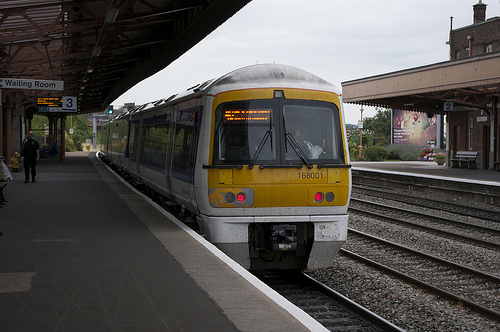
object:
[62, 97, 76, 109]
sign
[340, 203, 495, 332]
tracks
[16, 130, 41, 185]
person standing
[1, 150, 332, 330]
train platform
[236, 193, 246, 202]
headlight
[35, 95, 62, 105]
sign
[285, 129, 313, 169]
windshield wiper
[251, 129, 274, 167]
windshield wiper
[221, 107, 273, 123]
orange sign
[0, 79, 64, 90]
sign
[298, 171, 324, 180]
print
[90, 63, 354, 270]
train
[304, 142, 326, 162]
bag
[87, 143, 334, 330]
curb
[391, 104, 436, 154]
clock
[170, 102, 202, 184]
window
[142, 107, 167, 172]
window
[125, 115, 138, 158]
window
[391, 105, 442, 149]
poster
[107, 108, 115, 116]
signal light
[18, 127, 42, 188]
man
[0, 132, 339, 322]
platform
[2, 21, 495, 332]
station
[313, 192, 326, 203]
red light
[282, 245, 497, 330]
track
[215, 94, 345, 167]
train windshield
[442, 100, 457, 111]
sign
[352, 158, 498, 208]
platform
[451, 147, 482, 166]
bench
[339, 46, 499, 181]
train station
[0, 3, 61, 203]
train station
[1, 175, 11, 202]
bench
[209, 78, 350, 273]
front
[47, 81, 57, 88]
letters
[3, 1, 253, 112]
roof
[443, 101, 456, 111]
number